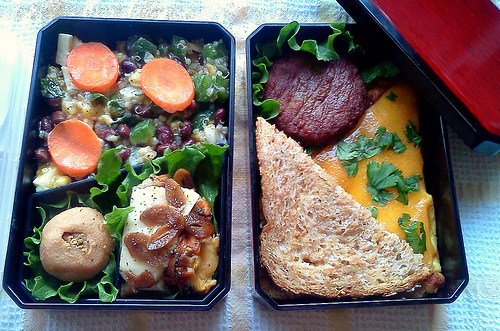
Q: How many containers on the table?
A: 2.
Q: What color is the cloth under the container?
A: White.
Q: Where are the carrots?
A: In the container on the left.